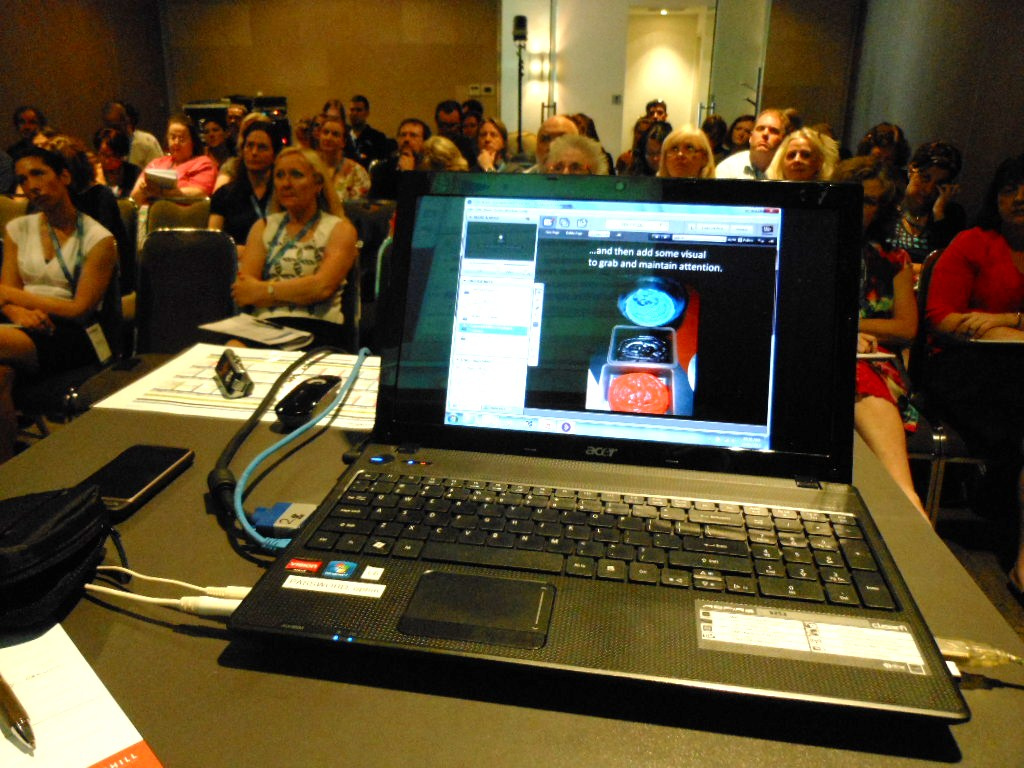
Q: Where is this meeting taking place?
A: In a conference room.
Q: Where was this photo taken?
A: In a meeting.